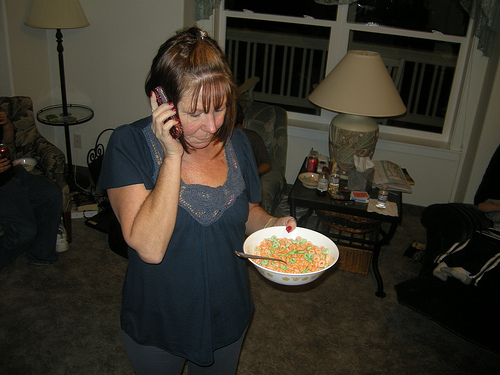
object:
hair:
[146, 18, 236, 139]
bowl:
[296, 172, 321, 189]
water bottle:
[329, 157, 341, 197]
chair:
[9, 86, 75, 257]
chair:
[392, 198, 499, 337]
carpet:
[242, 283, 462, 374]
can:
[292, 152, 327, 179]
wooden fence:
[228, 27, 457, 115]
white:
[227, 27, 459, 135]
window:
[216, 0, 481, 150]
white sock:
[431, 260, 473, 288]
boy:
[429, 192, 498, 286]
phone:
[155, 86, 200, 149]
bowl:
[236, 223, 341, 291]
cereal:
[268, 241, 310, 269]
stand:
[281, 143, 418, 303]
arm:
[255, 167, 272, 176]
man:
[236, 105, 275, 169]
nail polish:
[286, 223, 295, 233]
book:
[62, 183, 118, 210]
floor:
[20, 178, 499, 361]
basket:
[320, 210, 379, 276]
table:
[285, 155, 402, 274]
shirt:
[97, 144, 299, 362]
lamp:
[306, 48, 408, 181]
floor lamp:
[24, 9, 97, 216]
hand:
[147, 86, 195, 157]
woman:
[99, 24, 297, 373]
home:
[1, 2, 484, 372]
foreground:
[0, 22, 484, 366]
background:
[2, 3, 483, 302]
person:
[0, 102, 64, 291]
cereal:
[13, 155, 36, 171]